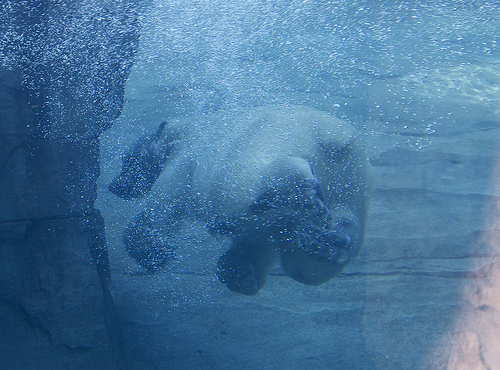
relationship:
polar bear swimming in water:
[101, 102, 377, 295] [2, 0, 497, 369]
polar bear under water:
[101, 102, 377, 295] [2, 0, 497, 369]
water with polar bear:
[2, 0, 497, 369] [101, 102, 377, 295]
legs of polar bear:
[261, 158, 366, 269] [101, 102, 377, 295]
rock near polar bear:
[2, 2, 152, 369] [101, 102, 377, 295]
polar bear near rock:
[101, 102, 377, 295] [2, 2, 152, 369]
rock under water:
[2, 2, 152, 369] [2, 0, 497, 369]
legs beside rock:
[261, 158, 366, 269] [2, 2, 152, 369]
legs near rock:
[261, 158, 366, 269] [2, 2, 152, 369]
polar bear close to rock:
[101, 102, 377, 295] [2, 2, 152, 369]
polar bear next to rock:
[101, 102, 377, 295] [2, 2, 152, 369]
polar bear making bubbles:
[101, 102, 377, 295] [0, 0, 498, 363]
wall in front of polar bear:
[0, 3, 148, 370] [101, 102, 377, 298]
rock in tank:
[2, 2, 152, 369] [0, 3, 498, 370]